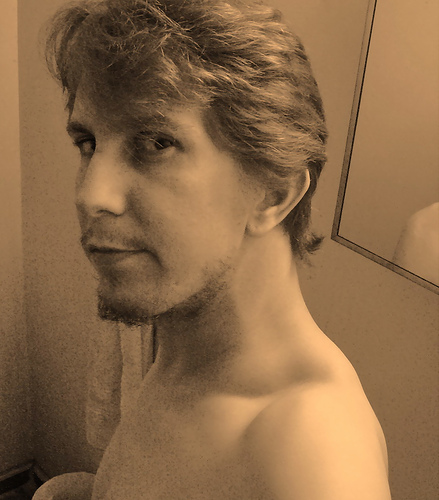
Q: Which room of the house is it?
A: It is a bathroom.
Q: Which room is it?
A: It is a bathroom.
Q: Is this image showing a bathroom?
A: Yes, it is showing a bathroom.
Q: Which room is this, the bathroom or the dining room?
A: It is the bathroom.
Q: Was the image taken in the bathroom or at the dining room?
A: It was taken at the bathroom.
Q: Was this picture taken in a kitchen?
A: No, the picture was taken in a bathroom.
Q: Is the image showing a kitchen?
A: No, the picture is showing a bathroom.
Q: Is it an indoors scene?
A: Yes, it is indoors.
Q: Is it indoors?
A: Yes, it is indoors.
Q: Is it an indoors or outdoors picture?
A: It is indoors.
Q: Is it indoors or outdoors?
A: It is indoors.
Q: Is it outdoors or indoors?
A: It is indoors.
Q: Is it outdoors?
A: No, it is indoors.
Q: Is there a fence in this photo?
A: No, there are no fences.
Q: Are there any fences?
A: No, there are no fences.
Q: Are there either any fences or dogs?
A: No, there are no fences or dogs.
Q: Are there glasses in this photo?
A: No, there are no glasses.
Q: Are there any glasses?
A: No, there are no glasses.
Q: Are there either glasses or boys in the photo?
A: No, there are no glasses or boys.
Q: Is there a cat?
A: No, there are no cats.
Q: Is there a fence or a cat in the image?
A: No, there are no cats or fences.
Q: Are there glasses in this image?
A: No, there are no glasses.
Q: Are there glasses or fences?
A: No, there are no glasses or fences.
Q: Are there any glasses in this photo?
A: No, there are no glasses.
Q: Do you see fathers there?
A: No, there are no fathers.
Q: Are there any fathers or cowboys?
A: No, there are no fathers or cowboys.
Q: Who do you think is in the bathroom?
A: The man is in the bathroom.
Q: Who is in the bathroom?
A: The man is in the bathroom.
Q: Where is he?
A: The man is in the bathroom.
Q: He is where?
A: The man is in the bathroom.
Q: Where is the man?
A: The man is in the bathroom.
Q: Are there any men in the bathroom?
A: Yes, there is a man in the bathroom.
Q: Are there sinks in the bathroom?
A: No, there is a man in the bathroom.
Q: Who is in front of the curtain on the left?
A: The man is in front of the curtain.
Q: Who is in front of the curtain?
A: The man is in front of the curtain.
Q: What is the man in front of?
A: The man is in front of the curtain.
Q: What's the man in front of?
A: The man is in front of the curtain.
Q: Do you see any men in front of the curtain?
A: Yes, there is a man in front of the curtain.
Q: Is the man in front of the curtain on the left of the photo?
A: Yes, the man is in front of the curtain.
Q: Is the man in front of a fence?
A: No, the man is in front of the curtain.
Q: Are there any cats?
A: No, there are no cats.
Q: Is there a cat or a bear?
A: No, there are no cats or bears.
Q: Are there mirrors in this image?
A: Yes, there is a mirror.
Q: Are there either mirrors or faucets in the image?
A: Yes, there is a mirror.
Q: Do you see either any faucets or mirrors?
A: Yes, there is a mirror.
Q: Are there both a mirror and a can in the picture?
A: No, there is a mirror but no cans.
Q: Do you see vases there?
A: No, there are no vases.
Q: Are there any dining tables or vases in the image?
A: No, there are no vases or dining tables.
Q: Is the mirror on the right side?
A: Yes, the mirror is on the right of the image.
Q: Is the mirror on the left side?
A: No, the mirror is on the right of the image.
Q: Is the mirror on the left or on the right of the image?
A: The mirror is on the right of the image.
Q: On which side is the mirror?
A: The mirror is on the right of the image.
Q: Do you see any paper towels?
A: No, there are no paper towels.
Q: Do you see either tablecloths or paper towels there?
A: No, there are no paper towels or tablecloths.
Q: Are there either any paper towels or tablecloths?
A: No, there are no paper towels or tablecloths.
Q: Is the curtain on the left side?
A: Yes, the curtain is on the left of the image.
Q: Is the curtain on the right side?
A: No, the curtain is on the left of the image.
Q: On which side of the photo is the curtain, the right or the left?
A: The curtain is on the left of the image.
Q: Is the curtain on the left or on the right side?
A: The curtain is on the left of the image.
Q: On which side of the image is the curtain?
A: The curtain is on the left of the image.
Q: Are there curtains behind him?
A: Yes, there is a curtain behind the man.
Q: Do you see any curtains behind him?
A: Yes, there is a curtain behind the man.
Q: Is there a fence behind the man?
A: No, there is a curtain behind the man.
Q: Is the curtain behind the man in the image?
A: Yes, the curtain is behind the man.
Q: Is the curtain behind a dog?
A: No, the curtain is behind the man.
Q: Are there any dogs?
A: No, there are no dogs.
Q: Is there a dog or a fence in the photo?
A: No, there are no dogs or fences.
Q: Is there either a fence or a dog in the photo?
A: No, there are no dogs or fences.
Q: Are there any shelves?
A: No, there are no shelves.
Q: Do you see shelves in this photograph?
A: No, there are no shelves.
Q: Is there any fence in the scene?
A: No, there are no fences.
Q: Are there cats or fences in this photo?
A: No, there are no fences or cats.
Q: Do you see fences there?
A: No, there are no fences.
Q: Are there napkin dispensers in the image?
A: No, there are no napkin dispensers.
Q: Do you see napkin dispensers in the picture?
A: No, there are no napkin dispensers.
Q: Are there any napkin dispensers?
A: No, there are no napkin dispensers.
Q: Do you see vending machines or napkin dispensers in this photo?
A: No, there are no napkin dispensers or vending machines.